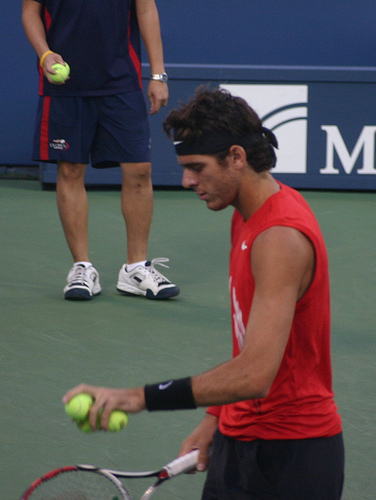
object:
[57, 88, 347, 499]
man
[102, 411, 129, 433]
balls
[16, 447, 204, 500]
racket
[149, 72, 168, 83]
watch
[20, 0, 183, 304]
men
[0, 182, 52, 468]
court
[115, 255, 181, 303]
sneakers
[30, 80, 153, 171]
shorts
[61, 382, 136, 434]
hand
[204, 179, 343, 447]
shirt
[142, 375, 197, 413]
armband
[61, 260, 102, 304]
shoes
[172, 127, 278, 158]
headband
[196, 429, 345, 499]
shorts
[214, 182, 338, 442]
tank top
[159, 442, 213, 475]
handle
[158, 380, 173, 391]
logo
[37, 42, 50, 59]
wrist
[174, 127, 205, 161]
forehead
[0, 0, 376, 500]
game